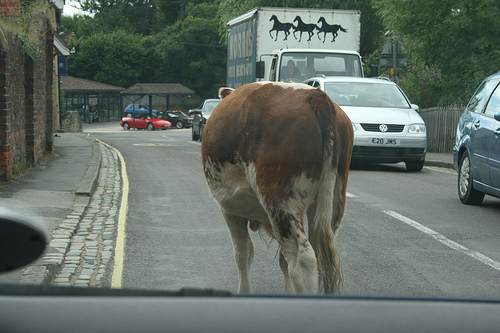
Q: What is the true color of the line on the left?
A: Yellow.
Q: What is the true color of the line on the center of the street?
A: White.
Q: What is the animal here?
A: Cow.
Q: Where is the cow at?
A: A street.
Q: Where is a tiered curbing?
A: Left of street.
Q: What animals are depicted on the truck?
A: Horses.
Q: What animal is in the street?
A: Cow.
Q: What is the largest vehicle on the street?
A: Truck.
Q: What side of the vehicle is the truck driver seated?
A: Right side (viewer's left).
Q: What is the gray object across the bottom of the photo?
A: Dashboard.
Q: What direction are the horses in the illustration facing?
A: Left.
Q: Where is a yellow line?
A: Left of street.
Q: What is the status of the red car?
A: Parked.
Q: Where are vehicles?
A: On the road.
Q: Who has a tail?
A: A cow.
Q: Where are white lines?
A: On the road.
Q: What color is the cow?
A: Brown and white.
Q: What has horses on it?
A: The box truck.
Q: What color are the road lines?
A: Yellow and white.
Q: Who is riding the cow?
A: No one.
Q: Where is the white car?
A: On the right side.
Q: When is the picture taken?
A: During the day.